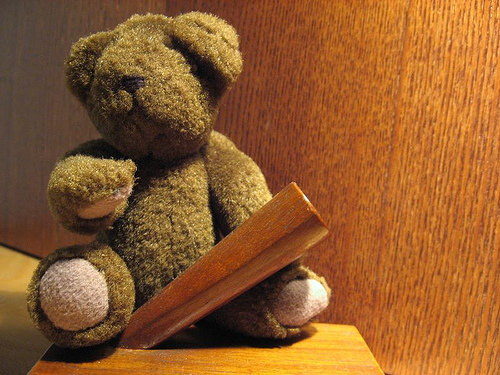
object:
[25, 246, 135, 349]
foot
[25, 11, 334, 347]
bear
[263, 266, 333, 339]
foot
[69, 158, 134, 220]
paw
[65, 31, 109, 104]
ear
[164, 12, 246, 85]
ear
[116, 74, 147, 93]
nose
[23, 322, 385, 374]
stand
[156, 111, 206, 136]
mouth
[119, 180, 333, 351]
wood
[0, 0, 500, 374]
wall